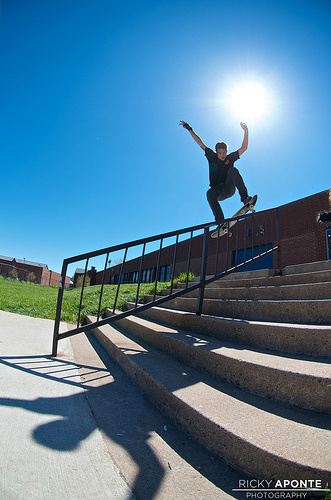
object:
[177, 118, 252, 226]
boy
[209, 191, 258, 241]
skateboard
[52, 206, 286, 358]
handrail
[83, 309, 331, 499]
stairs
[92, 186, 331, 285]
building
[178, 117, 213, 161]
arms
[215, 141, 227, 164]
head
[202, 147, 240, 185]
shirt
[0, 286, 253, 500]
shadow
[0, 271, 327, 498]
ground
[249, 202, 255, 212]
wheels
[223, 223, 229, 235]
wheels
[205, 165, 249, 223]
blue jeans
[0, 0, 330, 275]
sky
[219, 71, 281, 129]
sun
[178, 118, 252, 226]
person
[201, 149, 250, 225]
clothes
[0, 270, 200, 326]
field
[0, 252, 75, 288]
building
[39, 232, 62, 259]
clouds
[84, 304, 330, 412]
steps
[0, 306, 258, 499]
sidewalk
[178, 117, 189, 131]
hand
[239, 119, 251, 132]
hand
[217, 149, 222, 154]
eye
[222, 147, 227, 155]
eye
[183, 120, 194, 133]
protective gear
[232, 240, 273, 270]
door